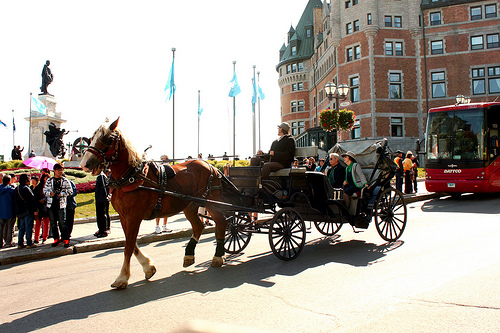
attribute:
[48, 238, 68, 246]
shoes — red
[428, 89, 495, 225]
bus — red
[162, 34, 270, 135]
flags — blue, bright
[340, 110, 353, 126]
lamps — old fashioned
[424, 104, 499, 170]
front window — large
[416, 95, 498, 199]
bus — red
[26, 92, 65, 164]
pedestal — white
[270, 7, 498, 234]
building — large, brown, brick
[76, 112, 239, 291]
horse — white, brown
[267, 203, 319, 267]
wheel — round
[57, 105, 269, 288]
horse — large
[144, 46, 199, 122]
flags — blue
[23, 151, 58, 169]
umbrella — pink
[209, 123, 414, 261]
carriage — open